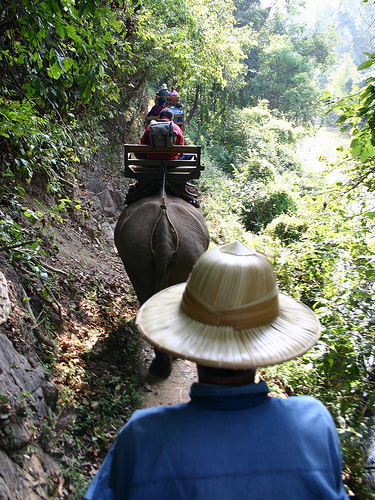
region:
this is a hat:
[166, 246, 290, 349]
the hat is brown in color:
[183, 243, 284, 346]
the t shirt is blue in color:
[159, 406, 304, 498]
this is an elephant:
[122, 191, 194, 264]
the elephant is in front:
[126, 191, 202, 251]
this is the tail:
[150, 229, 174, 274]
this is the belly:
[186, 210, 204, 237]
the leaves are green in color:
[326, 319, 359, 377]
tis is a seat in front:
[124, 142, 202, 183]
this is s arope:
[155, 205, 168, 216]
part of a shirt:
[195, 463, 215, 498]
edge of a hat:
[236, 359, 254, 365]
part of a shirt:
[213, 445, 245, 483]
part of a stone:
[9, 450, 48, 482]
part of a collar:
[226, 384, 250, 407]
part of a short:
[229, 413, 266, 471]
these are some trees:
[16, 6, 252, 87]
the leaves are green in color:
[22, 58, 77, 107]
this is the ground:
[57, 232, 85, 260]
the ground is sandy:
[58, 227, 111, 275]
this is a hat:
[133, 231, 332, 366]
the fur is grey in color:
[126, 203, 145, 226]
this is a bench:
[125, 143, 202, 179]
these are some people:
[145, 86, 183, 141]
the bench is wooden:
[196, 145, 201, 174]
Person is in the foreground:
[65, 236, 365, 496]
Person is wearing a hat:
[120, 234, 335, 375]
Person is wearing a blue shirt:
[75, 377, 358, 499]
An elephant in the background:
[109, 180, 214, 383]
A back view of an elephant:
[108, 182, 215, 382]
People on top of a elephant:
[117, 78, 209, 203]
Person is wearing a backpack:
[143, 113, 176, 153]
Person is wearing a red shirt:
[136, 113, 186, 164]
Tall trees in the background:
[4, 3, 374, 181]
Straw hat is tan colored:
[119, 236, 336, 380]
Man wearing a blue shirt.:
[92, 368, 358, 493]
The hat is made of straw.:
[127, 214, 342, 376]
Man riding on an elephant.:
[105, 98, 212, 175]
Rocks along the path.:
[5, 269, 70, 499]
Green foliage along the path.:
[0, 14, 169, 104]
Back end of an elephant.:
[106, 183, 221, 290]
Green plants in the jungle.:
[222, 148, 296, 235]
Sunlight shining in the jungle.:
[261, 19, 325, 193]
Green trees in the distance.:
[232, 26, 339, 118]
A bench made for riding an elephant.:
[112, 139, 226, 186]